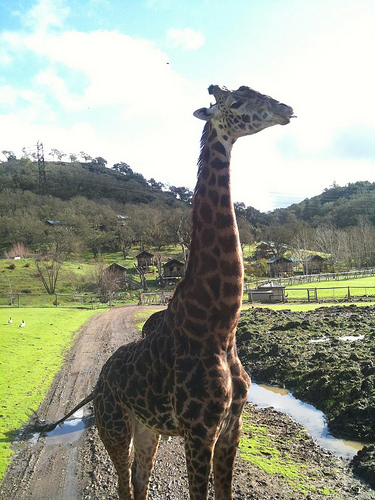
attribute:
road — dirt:
[3, 309, 215, 498]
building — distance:
[129, 242, 170, 269]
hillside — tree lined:
[5, 152, 171, 252]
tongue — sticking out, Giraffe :
[288, 112, 298, 122]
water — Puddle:
[260, 385, 281, 404]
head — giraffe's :
[185, 79, 296, 150]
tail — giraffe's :
[28, 391, 96, 439]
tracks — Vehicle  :
[42, 328, 118, 497]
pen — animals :
[287, 278, 362, 291]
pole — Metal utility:
[35, 137, 56, 205]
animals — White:
[11, 249, 27, 263]